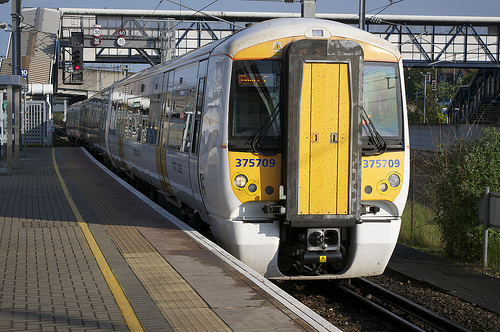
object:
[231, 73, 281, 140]
window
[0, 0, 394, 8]
sky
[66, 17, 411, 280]
car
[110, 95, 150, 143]
window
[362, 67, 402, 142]
window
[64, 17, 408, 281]
track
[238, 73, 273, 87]
lights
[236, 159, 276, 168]
blue numbers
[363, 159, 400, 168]
blue numbers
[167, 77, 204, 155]
window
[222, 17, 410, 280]
train front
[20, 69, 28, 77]
sign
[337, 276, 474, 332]
rails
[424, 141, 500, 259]
bush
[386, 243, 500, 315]
platform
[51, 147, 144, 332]
yellow line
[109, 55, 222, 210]
reflection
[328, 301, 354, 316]
cobblestone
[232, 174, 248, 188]
light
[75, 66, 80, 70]
light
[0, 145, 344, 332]
platform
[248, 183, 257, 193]
light